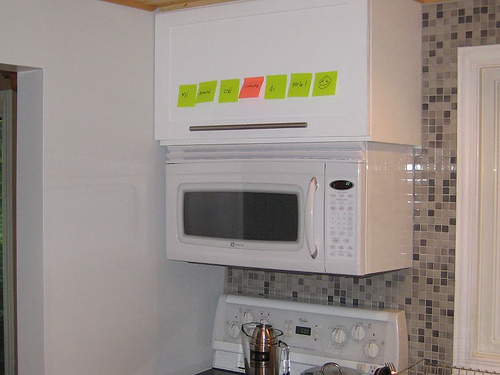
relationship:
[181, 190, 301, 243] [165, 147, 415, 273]
glass door on microwave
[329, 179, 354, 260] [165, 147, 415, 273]
display panel on microwave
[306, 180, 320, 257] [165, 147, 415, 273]
handle on microwave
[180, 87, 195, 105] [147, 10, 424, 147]
post it note stuck on cabinet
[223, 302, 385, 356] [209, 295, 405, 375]
display panel on stove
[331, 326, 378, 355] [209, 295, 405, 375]
control knobs on stove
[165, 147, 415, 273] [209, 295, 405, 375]
microwave over stove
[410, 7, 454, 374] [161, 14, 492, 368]
tile on wall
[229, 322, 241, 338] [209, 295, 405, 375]
knob on oven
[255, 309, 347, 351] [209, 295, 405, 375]
oven control panel on stove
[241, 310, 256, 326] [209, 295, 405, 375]
knob on stove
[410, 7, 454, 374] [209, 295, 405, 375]
tile behind stove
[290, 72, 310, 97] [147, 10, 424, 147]
post it note on cabinet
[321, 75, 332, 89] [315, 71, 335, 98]
smiley face on post it note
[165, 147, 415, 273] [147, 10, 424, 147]
microwave under cabinet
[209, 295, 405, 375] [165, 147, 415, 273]
oven under microwave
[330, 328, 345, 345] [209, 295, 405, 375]
dial on stove